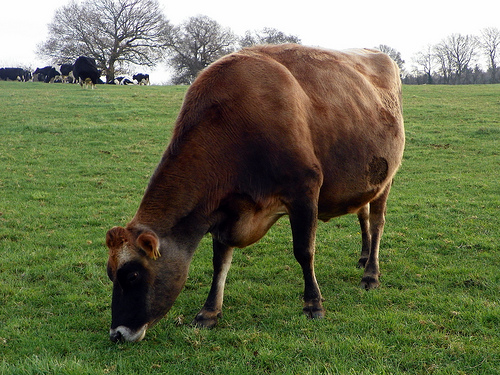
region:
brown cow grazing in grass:
[94, 35, 414, 355]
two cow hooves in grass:
[187, 293, 331, 330]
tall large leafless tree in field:
[40, 3, 175, 88]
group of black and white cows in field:
[3, 52, 153, 96]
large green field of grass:
[1, 73, 498, 369]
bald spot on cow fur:
[364, 146, 390, 194]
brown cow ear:
[131, 227, 163, 262]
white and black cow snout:
[106, 318, 151, 346]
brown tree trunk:
[98, 59, 120, 89]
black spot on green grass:
[458, 230, 495, 259]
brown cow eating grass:
[71, 43, 394, 332]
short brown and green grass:
[5, 146, 76, 201]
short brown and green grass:
[41, 240, 83, 290]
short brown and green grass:
[246, 339, 295, 362]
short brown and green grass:
[335, 291, 383, 340]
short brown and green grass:
[381, 266, 425, 341]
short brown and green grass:
[422, 197, 483, 277]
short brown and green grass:
[45, 76, 134, 164]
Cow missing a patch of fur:
[361, 155, 391, 193]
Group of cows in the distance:
[0, 54, 168, 101]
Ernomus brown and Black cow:
[67, 40, 436, 352]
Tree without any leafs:
[34, 1, 194, 72]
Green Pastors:
[20, 160, 79, 296]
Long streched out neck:
[111, 135, 233, 235]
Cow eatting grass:
[87, 230, 164, 351]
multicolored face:
[96, 225, 189, 351]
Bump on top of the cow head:
[101, 221, 131, 257]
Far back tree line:
[392, 38, 498, 110]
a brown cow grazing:
[106, 43, 402, 347]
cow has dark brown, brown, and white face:
[105, 45, 407, 344]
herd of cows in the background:
[1, 55, 150, 87]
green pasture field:
[1, 83, 499, 372]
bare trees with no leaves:
[33, 18, 496, 83]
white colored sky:
[0, 1, 495, 83]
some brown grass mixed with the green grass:
[2, 83, 494, 371]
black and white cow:
[132, 72, 149, 87]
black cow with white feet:
[71, 55, 102, 91]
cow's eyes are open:
[105, 45, 405, 346]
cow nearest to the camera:
[87, 35, 411, 350]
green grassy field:
[3, 77, 497, 374]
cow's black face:
[103, 258, 153, 352]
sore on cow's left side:
[368, 147, 390, 185]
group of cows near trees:
[1, 56, 156, 98]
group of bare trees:
[43, 2, 499, 96]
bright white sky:
[3, 3, 499, 88]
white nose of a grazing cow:
[109, 321, 154, 346]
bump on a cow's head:
[106, 220, 130, 255]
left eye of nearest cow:
[124, 266, 141, 285]